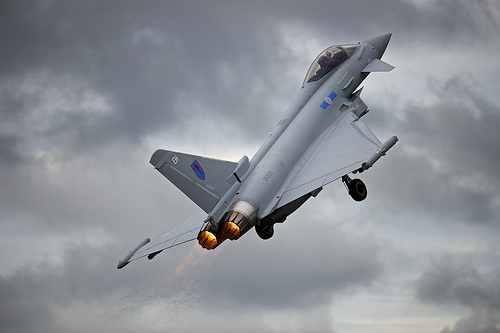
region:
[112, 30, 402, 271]
Grey fight jet with logo on tail.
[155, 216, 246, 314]
Engine exhaust with flames.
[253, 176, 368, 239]
Pair of landing gear.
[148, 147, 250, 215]
Jet rudder with red and blue logo.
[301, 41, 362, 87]
Fighter jet cockpit.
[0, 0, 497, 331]
Gray cloudy sky with jet flying through.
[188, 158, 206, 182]
Blue emblem with red trim.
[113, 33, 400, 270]
Fighter jet with nose pointing towards the sky.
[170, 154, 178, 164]
White letters spelling EH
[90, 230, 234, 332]
Shimmering heat exhaust.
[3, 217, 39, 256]
gray cloud in sky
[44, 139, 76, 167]
gray cloud in sky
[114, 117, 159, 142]
gray cloud in sky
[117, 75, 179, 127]
gray cloud in sky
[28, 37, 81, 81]
gray cloud in sky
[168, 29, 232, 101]
gray cloud in sky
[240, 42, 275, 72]
gray cloud in sky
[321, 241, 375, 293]
gray cloud in sky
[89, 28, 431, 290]
airplane in the sk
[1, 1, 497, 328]
gray clouds in the sky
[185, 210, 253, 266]
two pipes on the back of the plane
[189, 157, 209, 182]
blue and red design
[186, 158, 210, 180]
design on the tail of the plane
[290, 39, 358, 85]
cockpit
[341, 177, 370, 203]
wheel under the plane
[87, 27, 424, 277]
gray plane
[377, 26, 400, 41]
sharp point on the nose of the plane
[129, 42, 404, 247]
plane is in the air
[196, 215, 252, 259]
lights are red in color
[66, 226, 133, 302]
sky is dark blu in color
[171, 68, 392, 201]
plane is grey in color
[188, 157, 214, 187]
plane has blue logos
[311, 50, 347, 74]
a man is in th plane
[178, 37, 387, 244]
plane going up in the air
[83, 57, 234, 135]
sky covered of dark clouds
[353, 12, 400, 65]
pl;ane nose is dark grey in color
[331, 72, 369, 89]
plane has yellow marks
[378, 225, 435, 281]
A cloud in the sky.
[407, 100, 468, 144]
A cloud in the sky.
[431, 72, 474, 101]
A cloud in the sky.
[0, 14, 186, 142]
A cloud in the sky.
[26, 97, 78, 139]
A cloud in the sky.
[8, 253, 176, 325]
A cloud in the sky.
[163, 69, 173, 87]
A cloud in the sky.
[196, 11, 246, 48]
A cloud in the sky.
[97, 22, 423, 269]
A fighter aircraft with an afterburner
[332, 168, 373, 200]
Airplane landing gear with a black wheel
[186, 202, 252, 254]
An airplane afterburner that is on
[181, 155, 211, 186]
A blue shield-shaped logo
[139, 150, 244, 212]
The tailfin of an airplane with a logo on it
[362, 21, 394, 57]
The nosecone of an airplane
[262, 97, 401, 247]
The right wing of an airplane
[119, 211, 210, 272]
The left wing of an airplane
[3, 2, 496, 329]
A dark cloudy sky with an airplane in it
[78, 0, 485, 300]
this is a fighter jet